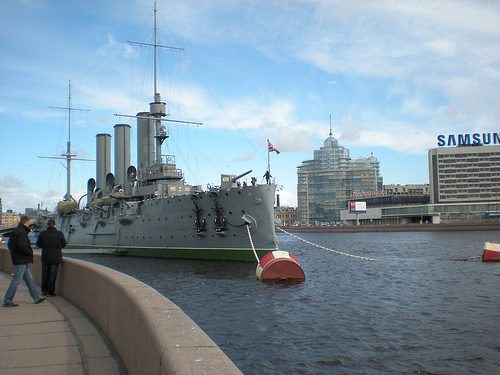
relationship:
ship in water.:
[32, 39, 277, 266] [205, 234, 497, 374]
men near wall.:
[6, 213, 66, 304] [66, 258, 165, 367]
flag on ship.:
[267, 138, 279, 157] [32, 39, 277, 266]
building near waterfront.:
[427, 146, 500, 224] [279, 220, 498, 252]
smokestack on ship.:
[111, 124, 133, 188] [32, 39, 277, 266]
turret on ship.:
[218, 169, 256, 183] [32, 39, 277, 266]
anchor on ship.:
[190, 200, 207, 235] [32, 39, 277, 266]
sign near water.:
[345, 199, 367, 212] [205, 234, 497, 374]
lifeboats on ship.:
[58, 199, 79, 215] [32, 39, 277, 266]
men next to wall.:
[6, 213, 66, 304] [66, 258, 165, 367]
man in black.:
[34, 226, 67, 293] [44, 234, 54, 245]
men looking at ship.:
[6, 213, 66, 304] [32, 39, 277, 266]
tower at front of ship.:
[149, 85, 182, 191] [32, 39, 277, 266]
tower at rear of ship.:
[63, 143, 76, 203] [32, 39, 277, 266]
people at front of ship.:
[225, 170, 272, 186] [32, 39, 277, 266]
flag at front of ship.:
[267, 138, 279, 157] [32, 39, 277, 266]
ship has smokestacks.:
[32, 39, 277, 266] [93, 132, 114, 200]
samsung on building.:
[434, 132, 500, 145] [427, 146, 500, 224]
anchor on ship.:
[208, 198, 229, 234] [32, 39, 277, 266]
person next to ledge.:
[34, 226, 67, 293] [62, 252, 234, 373]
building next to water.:
[427, 146, 500, 224] [205, 234, 497, 374]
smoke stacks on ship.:
[111, 124, 133, 188] [32, 39, 277, 266]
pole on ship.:
[269, 152, 271, 175] [32, 39, 277, 266]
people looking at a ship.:
[6, 213, 66, 304] [32, 39, 277, 266]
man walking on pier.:
[34, 226, 67, 293] [62, 252, 234, 373]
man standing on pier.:
[34, 226, 67, 293] [62, 252, 234, 373]